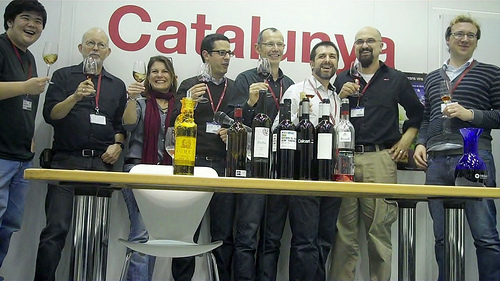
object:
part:
[133, 91, 185, 175]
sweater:
[119, 89, 190, 180]